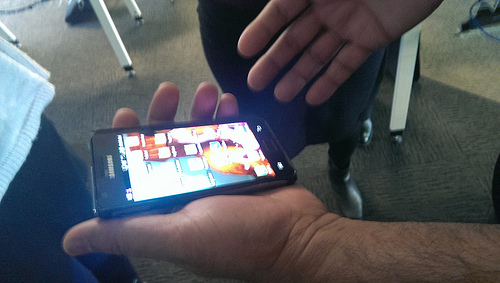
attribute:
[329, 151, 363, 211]
shoes — black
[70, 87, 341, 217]
cell phone — on, black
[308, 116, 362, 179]
tights — black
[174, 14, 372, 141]
skirt — black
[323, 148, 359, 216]
shoe — black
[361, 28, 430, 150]
leg — metal, white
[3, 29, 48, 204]
sweater — knit, white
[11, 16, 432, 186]
floor — carpeted, brown, grey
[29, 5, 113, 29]
shoe — black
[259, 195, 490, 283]
arm — hairy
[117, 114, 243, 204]
screen — lit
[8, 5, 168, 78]
legs — white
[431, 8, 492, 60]
cord — blue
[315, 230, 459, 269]
hair — black